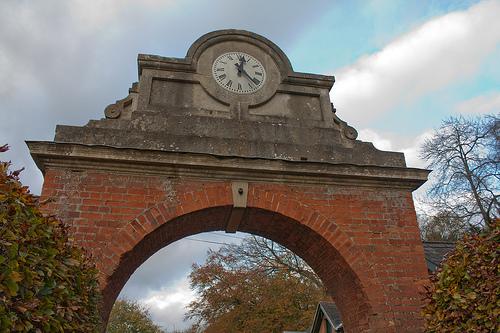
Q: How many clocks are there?
A: One.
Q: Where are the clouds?
A: In sky.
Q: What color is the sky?
A: Blue.